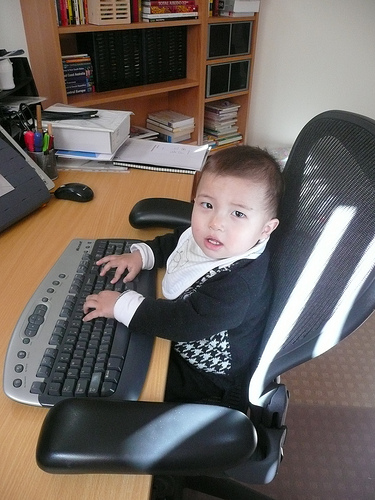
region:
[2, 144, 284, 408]
Toddler typing on a keyboard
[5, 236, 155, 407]
Dark and light gray computer keyboard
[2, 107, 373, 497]
Toddler sitting in an office chair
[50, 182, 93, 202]
Corded black computer mouse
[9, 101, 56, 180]
Scissors and markers in a metal holder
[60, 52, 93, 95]
Stack of thick books on a bookshelf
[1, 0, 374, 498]
Toddler sitting in a home office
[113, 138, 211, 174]
White folder on a black notebook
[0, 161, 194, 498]
Light wood pattern desk top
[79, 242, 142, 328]
Two baby hands on a keyboard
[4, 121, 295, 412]
the baby is playing on the keyboard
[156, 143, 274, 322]
the baby has a bib around his neck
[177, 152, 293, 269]
the child appears to be oriental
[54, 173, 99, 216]
a black mouse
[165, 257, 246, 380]
the baby's shirt is checked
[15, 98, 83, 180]
a pencil cup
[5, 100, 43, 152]
a scissor is in the pencil cup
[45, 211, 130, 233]
the desk is made of wood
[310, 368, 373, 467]
it appears there is carpet on the floor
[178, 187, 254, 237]
the baby has dark eyes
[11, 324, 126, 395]
Keyboard on the table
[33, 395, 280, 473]
A seat in the room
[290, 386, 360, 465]
A floor with tiles.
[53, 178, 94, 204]
A mouse on the table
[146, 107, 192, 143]
A table in the room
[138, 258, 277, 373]
A black and white sweater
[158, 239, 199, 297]
A white baby napkin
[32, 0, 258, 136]
A bookshelf in the photo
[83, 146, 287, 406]
A baby seated in the room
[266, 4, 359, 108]
A wall in the room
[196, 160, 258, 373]
little boy wearing a bib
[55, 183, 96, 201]
black computer mouse sitting on a desk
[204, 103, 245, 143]
stack of books on a shelf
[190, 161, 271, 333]
baby sitting in an office chair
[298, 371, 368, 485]
carpeted floor with a square pattern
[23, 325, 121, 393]
computer keyboard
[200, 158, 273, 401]
baby wearing a black and white sweater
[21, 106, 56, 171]
container of office supplies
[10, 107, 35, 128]
black scissors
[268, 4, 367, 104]
white wall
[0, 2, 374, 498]
baby sitting at a computer desk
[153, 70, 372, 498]
baby sitting in a black chair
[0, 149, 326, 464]
baby typing on a keyboard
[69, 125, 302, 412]
baby with short brown hair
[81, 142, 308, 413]
baby wearing a white bib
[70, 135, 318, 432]
baby wearing a black and white sweater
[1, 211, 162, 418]
silver and black keyboard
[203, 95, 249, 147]
stack of books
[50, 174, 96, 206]
black computer mouse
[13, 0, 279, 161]
tan book shelf